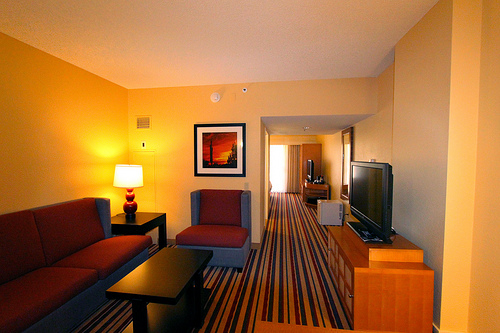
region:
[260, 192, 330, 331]
striped carpet flooring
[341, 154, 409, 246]
flat screen television set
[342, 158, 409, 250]
wide screen tv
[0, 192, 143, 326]
red and grey sofa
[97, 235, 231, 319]
black coffee table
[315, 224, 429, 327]
wooden dresser drawer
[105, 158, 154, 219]
red lamp with a white lampshade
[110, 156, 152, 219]
lamp providing light to the room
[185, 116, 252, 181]
photograph of a cactus on the wall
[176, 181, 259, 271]
red and grey chair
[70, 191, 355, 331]
blue, red and tan striped carpet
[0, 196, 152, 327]
A red modern sofa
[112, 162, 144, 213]
A red table lamp with white shade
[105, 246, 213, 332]
A black coffee table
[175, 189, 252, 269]
A gray and red modern chair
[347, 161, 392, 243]
A flat-screen TV that is off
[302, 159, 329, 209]
A black TV on a table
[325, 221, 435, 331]
A honey brown wooden TV stand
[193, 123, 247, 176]
A wall painting with black frame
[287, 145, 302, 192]
A window curtain that hangs to the floor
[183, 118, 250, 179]
picture in a frame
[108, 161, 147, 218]
table lamp with shade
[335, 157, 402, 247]
black plastic television set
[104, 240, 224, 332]
black coffee table made of wood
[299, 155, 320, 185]
black plastic television set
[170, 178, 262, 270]
grey and red chair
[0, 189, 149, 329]
grey and red couch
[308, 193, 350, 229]
small white fridge in a room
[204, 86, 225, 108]
white plastic smoke detector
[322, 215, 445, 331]
brown wooden dresser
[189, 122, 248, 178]
Photo in black frame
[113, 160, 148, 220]
Red circular stacked lamp.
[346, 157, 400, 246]
Flat screen tv on dresser.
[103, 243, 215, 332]
Black rectangular coffee table.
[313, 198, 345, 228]
Small and square fridge.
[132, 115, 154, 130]
Air vent on wall.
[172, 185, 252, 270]
red and grey chair.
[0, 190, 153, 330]
Red and grey couch.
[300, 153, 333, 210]
Tv atop a dresser in next room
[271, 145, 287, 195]
Window in next room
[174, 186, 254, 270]
red and blue seat in a hotel room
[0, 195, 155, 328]
red and blue couch in a hotel room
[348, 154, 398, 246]
flat screen tv on a dresser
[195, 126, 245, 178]
framed pictue of a sunset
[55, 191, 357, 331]
striped carpeting in the hotel room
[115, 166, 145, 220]
lamp turned on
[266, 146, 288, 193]
large window with sunight shining through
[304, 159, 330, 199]
tv on a dresser in the bedroom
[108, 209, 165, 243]
black side table